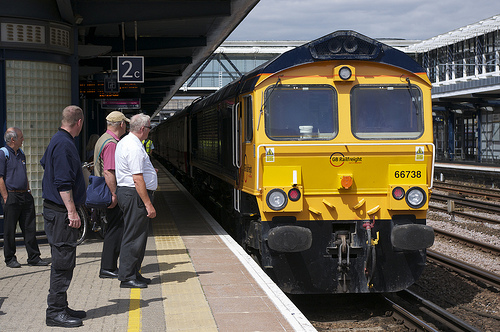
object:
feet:
[45, 308, 82, 327]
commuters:
[40, 105, 87, 328]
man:
[94, 111, 131, 278]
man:
[115, 113, 158, 288]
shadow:
[144, 248, 189, 256]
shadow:
[148, 270, 213, 285]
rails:
[384, 289, 500, 332]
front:
[254, 30, 435, 293]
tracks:
[425, 249, 499, 290]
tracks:
[427, 226, 500, 253]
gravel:
[439, 234, 483, 256]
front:
[0, 57, 75, 242]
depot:
[0, 0, 499, 332]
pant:
[37, 204, 81, 320]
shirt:
[39, 128, 86, 209]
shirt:
[114, 132, 158, 190]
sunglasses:
[144, 125, 153, 129]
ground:
[0, 155, 500, 331]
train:
[148, 29, 435, 294]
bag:
[84, 138, 115, 209]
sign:
[117, 56, 145, 83]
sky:
[225, 0, 500, 41]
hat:
[105, 110, 130, 122]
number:
[395, 170, 421, 178]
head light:
[338, 66, 352, 80]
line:
[126, 269, 142, 332]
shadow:
[139, 261, 191, 274]